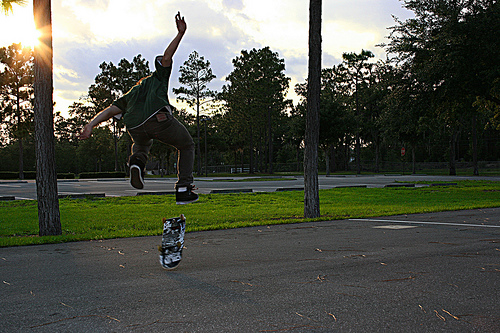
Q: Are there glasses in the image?
A: No, there are no glasses.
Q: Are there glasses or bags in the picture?
A: No, there are no glasses or bags.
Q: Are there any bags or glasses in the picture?
A: No, there are no glasses or bags.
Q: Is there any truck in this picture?
A: No, there are no trucks.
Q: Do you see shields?
A: No, there are no shields.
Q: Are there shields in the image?
A: No, there are no shields.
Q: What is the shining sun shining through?
A: The sun is shining through the clouds.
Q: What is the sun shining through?
A: The sun is shining through the clouds.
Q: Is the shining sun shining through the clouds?
A: Yes, the sun is shining through the clouds.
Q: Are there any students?
A: No, there are no students.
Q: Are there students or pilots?
A: No, there are no students or pilots.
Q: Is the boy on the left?
A: Yes, the boy is on the left of the image.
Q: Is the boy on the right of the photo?
A: No, the boy is on the left of the image.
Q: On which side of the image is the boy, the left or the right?
A: The boy is on the left of the image.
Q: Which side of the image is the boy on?
A: The boy is on the left of the image.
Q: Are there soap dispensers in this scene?
A: No, there are no soap dispensers.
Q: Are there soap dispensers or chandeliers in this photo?
A: No, there are no soap dispensers or chandeliers.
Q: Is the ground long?
A: Yes, the ground is long.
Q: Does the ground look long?
A: Yes, the ground is long.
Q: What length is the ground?
A: The ground is long.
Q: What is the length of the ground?
A: The ground is long.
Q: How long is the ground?
A: The ground is long.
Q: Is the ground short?
A: No, the ground is long.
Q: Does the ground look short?
A: No, the ground is long.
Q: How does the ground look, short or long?
A: The ground is long.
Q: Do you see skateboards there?
A: Yes, there is a skateboard.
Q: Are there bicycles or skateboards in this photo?
A: Yes, there is a skateboard.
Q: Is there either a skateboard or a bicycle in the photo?
A: Yes, there is a skateboard.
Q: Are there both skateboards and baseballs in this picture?
A: No, there is a skateboard but no baseballs.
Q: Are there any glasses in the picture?
A: No, there are no glasses.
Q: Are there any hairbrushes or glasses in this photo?
A: No, there are no glasses or hairbrushes.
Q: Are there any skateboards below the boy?
A: Yes, there is a skateboard below the boy.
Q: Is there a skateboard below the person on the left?
A: Yes, there is a skateboard below the boy.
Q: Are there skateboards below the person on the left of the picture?
A: Yes, there is a skateboard below the boy.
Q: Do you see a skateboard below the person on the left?
A: Yes, there is a skateboard below the boy.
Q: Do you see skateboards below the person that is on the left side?
A: Yes, there is a skateboard below the boy.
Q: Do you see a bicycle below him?
A: No, there is a skateboard below the boy.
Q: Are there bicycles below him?
A: No, there is a skateboard below the boy.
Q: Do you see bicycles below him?
A: No, there is a skateboard below the boy.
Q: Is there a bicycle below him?
A: No, there is a skateboard below the boy.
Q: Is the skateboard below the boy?
A: Yes, the skateboard is below the boy.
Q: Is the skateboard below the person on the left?
A: Yes, the skateboard is below the boy.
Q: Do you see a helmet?
A: No, there are no helmets.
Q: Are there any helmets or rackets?
A: No, there are no helmets or rackets.